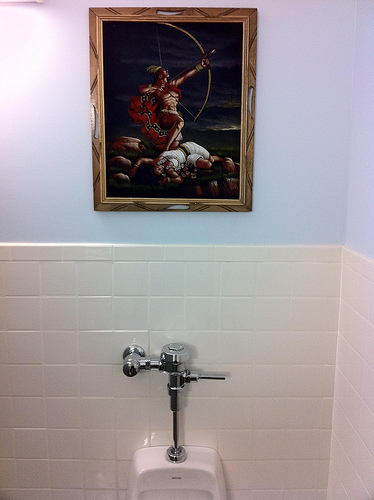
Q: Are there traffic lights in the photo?
A: No, there are no traffic lights.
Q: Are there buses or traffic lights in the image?
A: No, there are no traffic lights or buses.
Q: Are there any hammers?
A: No, there are no hammers.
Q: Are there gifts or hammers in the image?
A: No, there are no hammers or gifts.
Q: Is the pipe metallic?
A: Yes, the pipe is metallic.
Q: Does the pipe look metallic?
A: Yes, the pipe is metallic.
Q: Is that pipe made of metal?
A: Yes, the pipe is made of metal.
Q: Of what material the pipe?
A: The pipe is made of metal.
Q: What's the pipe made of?
A: The pipe is made of metal.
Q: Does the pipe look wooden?
A: No, the pipe is metallic.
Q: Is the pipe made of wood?
A: No, the pipe is made of metal.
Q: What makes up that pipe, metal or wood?
A: The pipe is made of metal.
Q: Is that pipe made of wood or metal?
A: The pipe is made of metal.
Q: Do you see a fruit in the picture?
A: Yes, there is a fruit.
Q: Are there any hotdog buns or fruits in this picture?
A: Yes, there is a fruit.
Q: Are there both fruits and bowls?
A: No, there is a fruit but no bowls.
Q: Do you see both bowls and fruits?
A: No, there is a fruit but no bowls.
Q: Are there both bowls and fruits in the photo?
A: No, there is a fruit but no bowls.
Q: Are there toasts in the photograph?
A: No, there are no toasts.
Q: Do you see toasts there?
A: No, there are no toasts.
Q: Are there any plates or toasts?
A: No, there are no toasts or plates.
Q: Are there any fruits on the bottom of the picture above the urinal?
A: Yes, there is a fruit on the bottom of the picture.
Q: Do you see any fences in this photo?
A: No, there are no fences.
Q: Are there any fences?
A: No, there are no fences.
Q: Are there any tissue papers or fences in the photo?
A: No, there are no fences or tissue papers.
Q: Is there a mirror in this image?
A: No, there are no mirrors.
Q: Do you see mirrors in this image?
A: No, there are no mirrors.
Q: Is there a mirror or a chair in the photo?
A: No, there are no mirrors or chairs.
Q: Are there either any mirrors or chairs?
A: No, there are no mirrors or chairs.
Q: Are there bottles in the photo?
A: No, there are no bottles.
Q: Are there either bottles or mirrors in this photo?
A: No, there are no bottles or mirrors.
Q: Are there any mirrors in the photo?
A: No, there are no mirrors.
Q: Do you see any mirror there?
A: No, there are no mirrors.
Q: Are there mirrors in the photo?
A: No, there are no mirrors.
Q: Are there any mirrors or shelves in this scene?
A: No, there are no mirrors or shelves.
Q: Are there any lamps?
A: No, there are no lamps.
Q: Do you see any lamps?
A: No, there are no lamps.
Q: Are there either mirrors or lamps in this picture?
A: No, there are no lamps or mirrors.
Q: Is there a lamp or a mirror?
A: No, there are no lamps or mirrors.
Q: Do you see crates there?
A: No, there are no crates.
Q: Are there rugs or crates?
A: No, there are no crates or rugs.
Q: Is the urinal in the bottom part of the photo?
A: Yes, the urinal is in the bottom of the image.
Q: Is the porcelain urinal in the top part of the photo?
A: No, the urinal is in the bottom of the image.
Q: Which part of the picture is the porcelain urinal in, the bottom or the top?
A: The urinal is in the bottom of the image.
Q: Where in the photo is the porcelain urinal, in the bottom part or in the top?
A: The urinal is in the bottom of the image.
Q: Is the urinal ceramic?
A: Yes, the urinal is ceramic.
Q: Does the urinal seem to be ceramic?
A: Yes, the urinal is ceramic.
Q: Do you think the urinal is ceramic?
A: Yes, the urinal is ceramic.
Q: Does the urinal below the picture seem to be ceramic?
A: Yes, the urinal is ceramic.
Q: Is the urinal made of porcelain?
A: Yes, the urinal is made of porcelain.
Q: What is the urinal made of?
A: The urinal is made of porcelain.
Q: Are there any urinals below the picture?
A: Yes, there is a urinal below the picture.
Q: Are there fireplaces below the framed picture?
A: No, there is a urinal below the picture.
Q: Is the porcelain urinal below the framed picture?
A: Yes, the urinal is below the picture.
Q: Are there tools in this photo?
A: No, there are no tools.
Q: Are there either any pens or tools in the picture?
A: No, there are no tools or pens.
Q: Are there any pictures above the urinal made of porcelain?
A: Yes, there is a picture above the urinal.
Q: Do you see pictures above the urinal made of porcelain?
A: Yes, there is a picture above the urinal.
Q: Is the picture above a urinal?
A: Yes, the picture is above a urinal.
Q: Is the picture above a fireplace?
A: No, the picture is above a urinal.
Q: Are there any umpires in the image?
A: No, there are no umpires.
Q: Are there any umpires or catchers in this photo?
A: No, there are no umpires or catchers.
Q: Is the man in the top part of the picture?
A: Yes, the man is in the top of the image.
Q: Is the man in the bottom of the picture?
A: No, the man is in the top of the image.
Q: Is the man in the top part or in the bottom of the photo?
A: The man is in the top of the image.